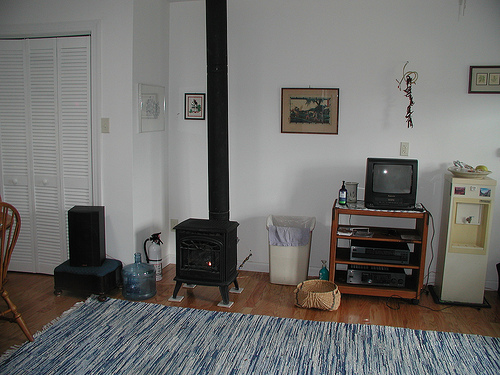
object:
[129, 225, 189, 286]
hydrant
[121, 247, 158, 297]
waterbottle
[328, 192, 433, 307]
stand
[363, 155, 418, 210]
t.v.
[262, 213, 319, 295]
bin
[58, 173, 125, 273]
speaker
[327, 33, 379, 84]
wall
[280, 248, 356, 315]
basket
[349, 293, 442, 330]
floor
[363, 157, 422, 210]
tv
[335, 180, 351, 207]
bottle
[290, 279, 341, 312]
basket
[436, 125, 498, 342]
cooler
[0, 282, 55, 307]
floor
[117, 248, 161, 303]
gallon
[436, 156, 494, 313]
water machine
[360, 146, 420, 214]
t.v.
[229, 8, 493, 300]
wall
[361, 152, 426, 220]
television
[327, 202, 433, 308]
stand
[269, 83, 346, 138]
picture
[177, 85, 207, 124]
picture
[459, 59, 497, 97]
picture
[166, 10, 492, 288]
wall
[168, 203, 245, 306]
oven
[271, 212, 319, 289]
trash can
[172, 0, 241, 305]
heater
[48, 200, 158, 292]
speaker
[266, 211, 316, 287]
trashcan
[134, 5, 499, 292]
wall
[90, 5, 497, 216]
wall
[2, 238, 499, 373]
floor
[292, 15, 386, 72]
wall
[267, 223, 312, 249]
washcloth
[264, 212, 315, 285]
trash can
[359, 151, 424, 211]
tv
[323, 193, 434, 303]
stool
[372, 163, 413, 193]
screen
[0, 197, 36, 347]
chair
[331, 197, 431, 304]
cabinet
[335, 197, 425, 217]
shelf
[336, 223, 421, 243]
shelf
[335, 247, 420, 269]
shelf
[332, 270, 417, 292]
shelf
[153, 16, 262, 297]
chimney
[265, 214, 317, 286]
dust bin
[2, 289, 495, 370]
carpet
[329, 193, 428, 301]
stand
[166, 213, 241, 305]
stove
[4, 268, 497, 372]
floor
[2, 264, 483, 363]
floor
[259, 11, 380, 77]
wall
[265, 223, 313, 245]
towel